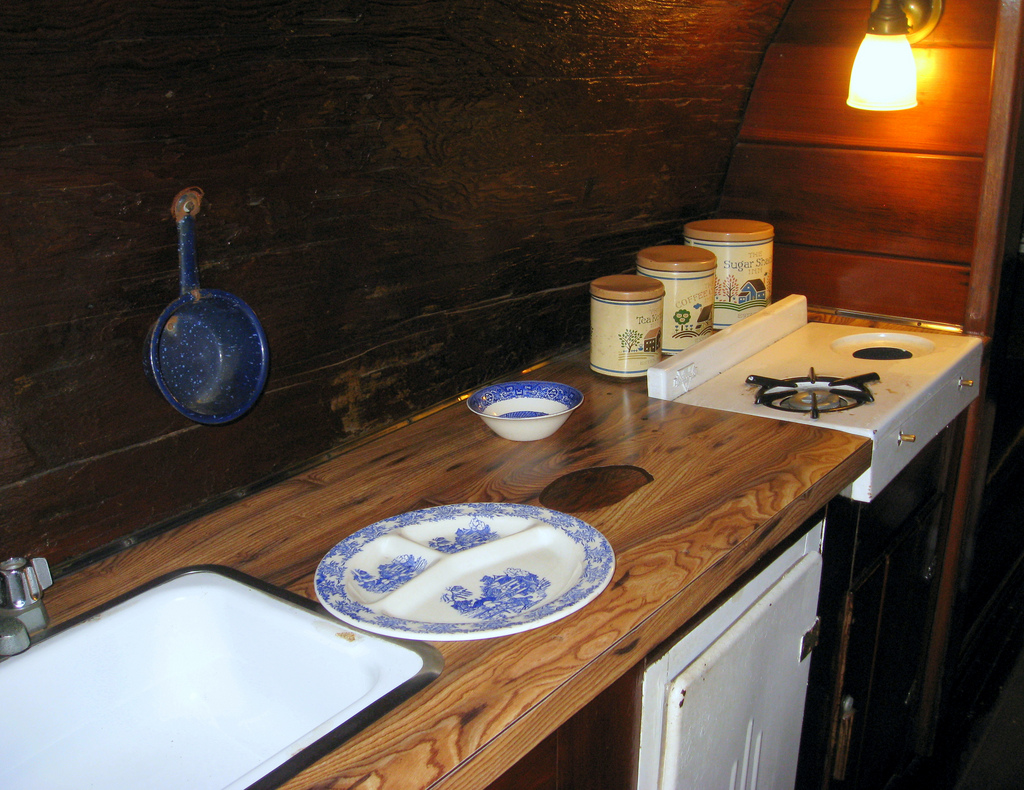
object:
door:
[657, 550, 822, 789]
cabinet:
[825, 404, 974, 790]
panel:
[713, 142, 988, 265]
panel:
[770, 245, 969, 330]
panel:
[737, 38, 998, 157]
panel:
[965, 427, 1024, 582]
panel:
[954, 570, 1023, 727]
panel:
[989, 264, 1024, 410]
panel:
[0, 0, 787, 584]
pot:
[141, 186, 268, 425]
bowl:
[465, 380, 585, 441]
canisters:
[589, 219, 775, 378]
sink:
[0, 564, 446, 790]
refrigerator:
[638, 524, 823, 789]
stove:
[645, 292, 984, 506]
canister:
[590, 274, 666, 377]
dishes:
[314, 503, 617, 641]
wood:
[715, 1, 996, 327]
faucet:
[0, 555, 53, 657]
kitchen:
[0, 0, 1024, 790]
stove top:
[743, 367, 880, 420]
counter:
[477, 665, 636, 790]